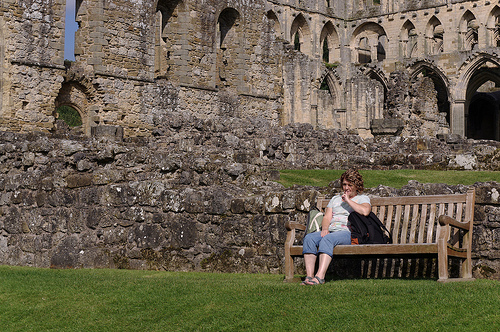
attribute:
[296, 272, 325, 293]
feet —  person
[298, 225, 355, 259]
capris — blue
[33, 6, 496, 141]
building — old, rock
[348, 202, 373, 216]
arm —  person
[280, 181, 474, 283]
bench — wooden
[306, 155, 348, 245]
person — leg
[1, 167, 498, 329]
grass — green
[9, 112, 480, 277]
wall — rock